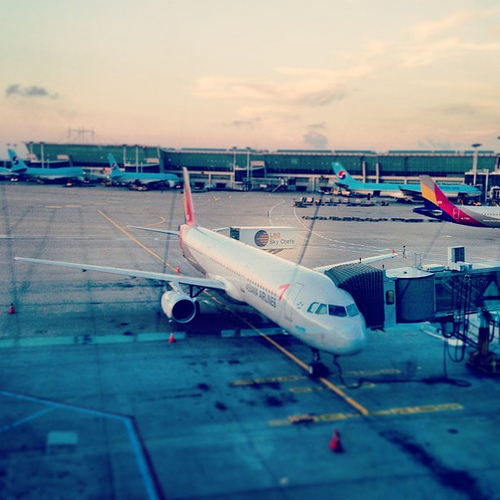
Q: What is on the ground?
A: The plane.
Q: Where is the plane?
A: At the airport.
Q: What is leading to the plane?
A: The terminal entry.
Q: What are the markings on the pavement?
A: Lines.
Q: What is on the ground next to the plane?
A: Cones.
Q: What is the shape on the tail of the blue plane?
A: A circle.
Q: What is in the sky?
A: Clouds.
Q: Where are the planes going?
A: To the terminals.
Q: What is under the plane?
A: Concrete.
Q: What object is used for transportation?
A: Airplane.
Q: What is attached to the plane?
A: Jetty.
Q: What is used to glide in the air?
A: Wings.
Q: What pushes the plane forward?
A: Engines.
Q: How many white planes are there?
A: One.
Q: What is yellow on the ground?
A: The lines.